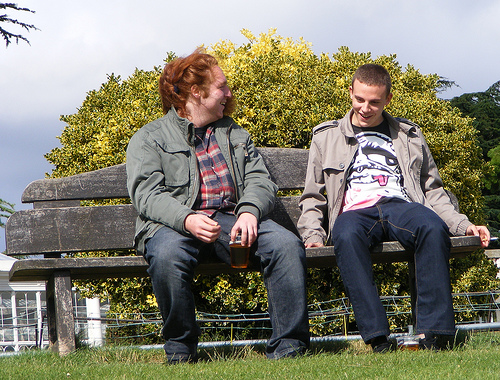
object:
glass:
[227, 239, 248, 268]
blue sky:
[0, 128, 59, 251]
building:
[0, 253, 101, 352]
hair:
[159, 42, 222, 118]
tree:
[36, 24, 499, 340]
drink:
[228, 239, 252, 269]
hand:
[180, 213, 221, 243]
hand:
[465, 223, 490, 250]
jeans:
[331, 196, 457, 343]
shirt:
[164, 127, 235, 219]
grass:
[0, 328, 498, 379]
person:
[123, 44, 309, 365]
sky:
[0, 0, 499, 260]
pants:
[141, 210, 309, 361]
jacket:
[296, 111, 473, 247]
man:
[295, 63, 490, 354]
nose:
[226, 86, 235, 98]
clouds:
[2, 0, 499, 142]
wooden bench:
[4, 147, 482, 355]